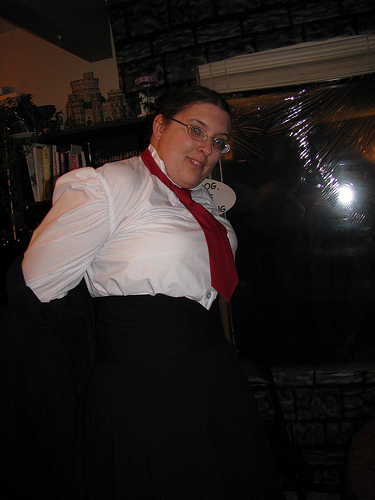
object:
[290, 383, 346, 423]
brick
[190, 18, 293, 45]
brick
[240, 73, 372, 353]
wall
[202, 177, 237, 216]
poster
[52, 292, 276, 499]
skirt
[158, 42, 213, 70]
wall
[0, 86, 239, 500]
lady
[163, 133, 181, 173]
light skinned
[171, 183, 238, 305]
tie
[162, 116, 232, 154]
spectacles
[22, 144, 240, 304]
shirt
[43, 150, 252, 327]
tucked in